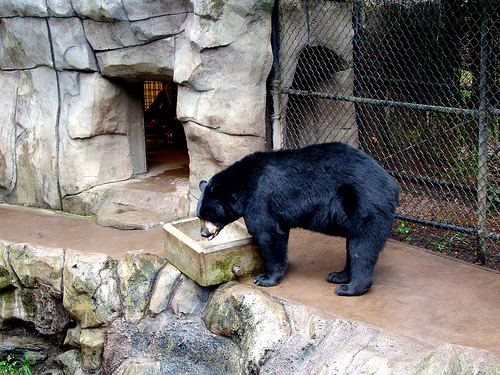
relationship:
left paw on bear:
[333, 280, 370, 296] [199, 141, 404, 296]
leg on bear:
[348, 222, 380, 301] [188, 111, 430, 324]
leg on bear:
[244, 215, 286, 285] [199, 141, 404, 296]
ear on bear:
[197, 177, 209, 192] [199, 141, 404, 296]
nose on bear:
[200, 228, 210, 239] [199, 141, 404, 296]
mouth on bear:
[201, 228, 221, 241] [199, 141, 404, 296]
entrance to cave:
[121, 74, 190, 187] [93, 49, 241, 230]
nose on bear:
[197, 226, 214, 242] [194, 144, 403, 316]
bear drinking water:
[190, 133, 417, 307] [179, 228, 218, 257]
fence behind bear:
[302, 14, 496, 174] [169, 94, 456, 336]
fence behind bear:
[267, 0, 500, 270] [199, 141, 404, 296]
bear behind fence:
[195, 141, 401, 297] [306, 10, 491, 153]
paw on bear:
[252, 268, 287, 290] [199, 141, 404, 296]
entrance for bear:
[269, 36, 366, 154] [166, 136, 408, 300]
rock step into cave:
[96, 168, 188, 228] [1, 0, 270, 228]